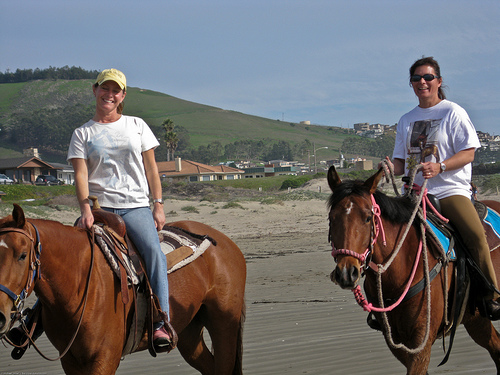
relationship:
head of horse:
[0, 192, 31, 334] [0, 202, 247, 375]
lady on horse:
[66, 67, 173, 346] [0, 202, 247, 375]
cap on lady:
[92, 67, 126, 87] [66, 67, 173, 346]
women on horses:
[377, 55, 498, 319] [0, 200, 251, 370]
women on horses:
[64, 67, 175, 348] [321, 160, 484, 371]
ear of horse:
[321, 162, 344, 195] [321, 187, 400, 299]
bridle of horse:
[326, 245, 443, 352] [321, 159, 498, 365]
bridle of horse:
[0, 263, 45, 335] [0, 190, 267, 352]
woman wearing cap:
[66, 67, 194, 295] [94, 58, 139, 105]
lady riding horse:
[388, 56, 500, 319] [312, 157, 440, 333]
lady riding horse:
[66, 67, 173, 346] [1, 209, 154, 358]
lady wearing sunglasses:
[388, 56, 500, 319] [410, 71, 440, 81]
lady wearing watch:
[66, 67, 173, 346] [150, 195, 164, 208]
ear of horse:
[9, 201, 28, 231] [0, 202, 247, 375]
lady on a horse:
[66, 67, 173, 346] [68, 67, 485, 350]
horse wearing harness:
[321, 159, 498, 365] [330, 183, 448, 310]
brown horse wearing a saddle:
[1, 203, 245, 373] [73, 215, 218, 290]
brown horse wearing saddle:
[315, 157, 495, 370] [400, 166, 497, 273]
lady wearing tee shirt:
[388, 52, 495, 241] [408, 111, 485, 189]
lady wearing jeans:
[66, 67, 173, 346] [84, 204, 172, 321]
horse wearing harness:
[0, 202, 247, 375] [2, 214, 42, 336]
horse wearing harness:
[321, 159, 498, 365] [319, 183, 388, 287]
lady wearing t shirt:
[66, 67, 173, 346] [66, 112, 158, 207]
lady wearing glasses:
[388, 56, 500, 319] [410, 74, 439, 82]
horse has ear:
[321, 159, 498, 365] [325, 165, 385, 193]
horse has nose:
[321, 159, 498, 365] [332, 251, 361, 289]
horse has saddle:
[2, 175, 272, 361] [413, 193, 496, 264]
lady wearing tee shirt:
[31, 90, 179, 263] [58, 113, 165, 218]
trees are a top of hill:
[2, 63, 104, 81] [3, 68, 332, 145]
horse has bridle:
[326, 165, 500, 368] [333, 165, 443, 353]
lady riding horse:
[66, 67, 173, 346] [0, 202, 247, 375]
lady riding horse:
[388, 56, 500, 319] [321, 159, 498, 365]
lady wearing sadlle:
[66, 67, 173, 346] [75, 195, 132, 253]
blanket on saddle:
[94, 225, 216, 285] [75, 215, 193, 354]